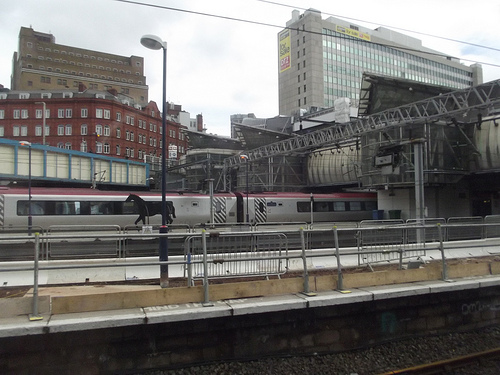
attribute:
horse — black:
[126, 193, 176, 227]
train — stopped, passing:
[1, 186, 378, 235]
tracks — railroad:
[4, 218, 500, 259]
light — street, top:
[140, 34, 169, 52]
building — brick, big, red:
[1, 88, 189, 177]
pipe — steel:
[412, 140, 424, 246]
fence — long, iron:
[2, 225, 498, 320]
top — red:
[2, 192, 374, 198]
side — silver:
[6, 197, 373, 219]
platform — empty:
[30, 281, 159, 308]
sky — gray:
[2, 2, 277, 129]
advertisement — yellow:
[277, 30, 291, 72]